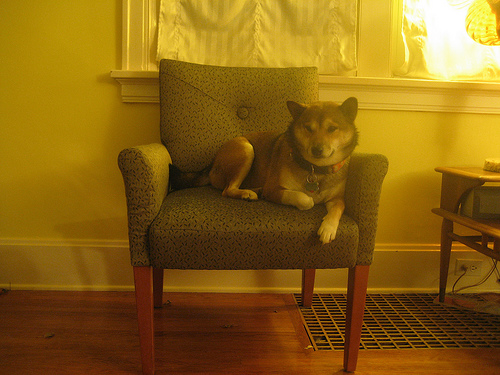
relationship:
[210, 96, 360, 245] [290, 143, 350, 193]
dog with collar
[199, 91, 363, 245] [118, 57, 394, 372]
dog sits in chair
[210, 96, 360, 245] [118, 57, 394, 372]
dog seated on chair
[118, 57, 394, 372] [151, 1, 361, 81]
chair below window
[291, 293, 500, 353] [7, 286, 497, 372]
grate in floor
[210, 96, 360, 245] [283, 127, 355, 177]
dog wearing collar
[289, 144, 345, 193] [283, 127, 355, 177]
collar on collar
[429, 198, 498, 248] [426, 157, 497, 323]
shelf on table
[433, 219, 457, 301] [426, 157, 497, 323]
leg on table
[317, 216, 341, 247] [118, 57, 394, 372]
front leg hanging off chair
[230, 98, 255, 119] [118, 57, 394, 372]
button on chair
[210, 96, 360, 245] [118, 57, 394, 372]
dog on chair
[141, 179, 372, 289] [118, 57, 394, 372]
cushions on chair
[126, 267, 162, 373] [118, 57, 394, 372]
legs on chair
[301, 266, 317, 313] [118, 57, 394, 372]
legs on chair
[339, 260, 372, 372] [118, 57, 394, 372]
legs on chair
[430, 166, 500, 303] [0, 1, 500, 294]
end table against wall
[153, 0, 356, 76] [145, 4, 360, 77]
covering on window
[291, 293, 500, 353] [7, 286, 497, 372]
grate on floor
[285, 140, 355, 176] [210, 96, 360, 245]
collar on dog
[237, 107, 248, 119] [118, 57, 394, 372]
button on chair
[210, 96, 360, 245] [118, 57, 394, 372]
dog resting on chair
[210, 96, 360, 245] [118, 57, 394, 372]
dog in chair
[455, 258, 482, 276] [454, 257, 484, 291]
cord with cord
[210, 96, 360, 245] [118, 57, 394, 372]
dog sitting on chair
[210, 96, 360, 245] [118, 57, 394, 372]
dog laying in a chair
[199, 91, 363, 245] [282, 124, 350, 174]
dog wearing collar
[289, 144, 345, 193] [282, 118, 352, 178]
collar are on collar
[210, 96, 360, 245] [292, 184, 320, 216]
dog bending h paw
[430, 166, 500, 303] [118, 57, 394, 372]
end table next to chair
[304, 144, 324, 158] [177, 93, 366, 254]
nose of dog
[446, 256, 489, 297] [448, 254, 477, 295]
cord plugged into outlet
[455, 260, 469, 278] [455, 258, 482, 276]
plug in an cord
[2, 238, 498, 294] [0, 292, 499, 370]
baseboard over floor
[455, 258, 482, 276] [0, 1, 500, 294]
cord in wall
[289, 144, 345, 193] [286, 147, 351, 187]
collar hanging from collar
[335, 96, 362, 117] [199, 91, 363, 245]
left ear of dog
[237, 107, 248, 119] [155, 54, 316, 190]
button in seat cushion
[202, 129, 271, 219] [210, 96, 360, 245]
hind leg of dog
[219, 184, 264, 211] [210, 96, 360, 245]
foot of dog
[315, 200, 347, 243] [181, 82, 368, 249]
front leg of dog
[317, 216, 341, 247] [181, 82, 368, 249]
front leg of dog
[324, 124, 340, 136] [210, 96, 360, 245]
eye of dog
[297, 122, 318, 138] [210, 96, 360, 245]
eye of dog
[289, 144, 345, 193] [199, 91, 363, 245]
collar around neck of dog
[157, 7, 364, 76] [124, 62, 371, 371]
covering directly behind chair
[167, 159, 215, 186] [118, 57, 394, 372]
tail on chair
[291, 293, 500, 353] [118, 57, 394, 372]
grate under chair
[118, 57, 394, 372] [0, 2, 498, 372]
chair against wall